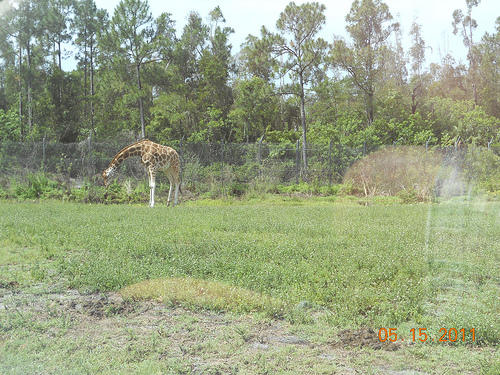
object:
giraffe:
[100, 135, 192, 206]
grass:
[1, 191, 499, 372]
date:
[376, 322, 484, 347]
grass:
[1, 171, 499, 202]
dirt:
[10, 286, 348, 363]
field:
[1, 173, 498, 373]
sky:
[1, 1, 499, 108]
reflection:
[95, 276, 281, 317]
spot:
[130, 146, 139, 154]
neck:
[108, 140, 141, 168]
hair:
[177, 185, 186, 197]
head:
[100, 163, 120, 187]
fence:
[2, 138, 500, 201]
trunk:
[293, 52, 313, 174]